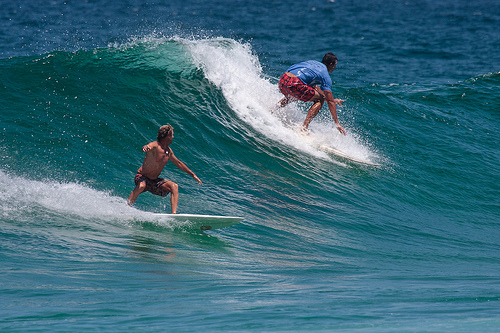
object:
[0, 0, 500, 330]
water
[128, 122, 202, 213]
man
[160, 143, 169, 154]
necklace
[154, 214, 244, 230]
surfboard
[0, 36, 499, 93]
wave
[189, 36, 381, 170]
whitecap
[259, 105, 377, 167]
surfer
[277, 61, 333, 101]
bathing suit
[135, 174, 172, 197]
shorts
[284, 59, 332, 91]
tshirt